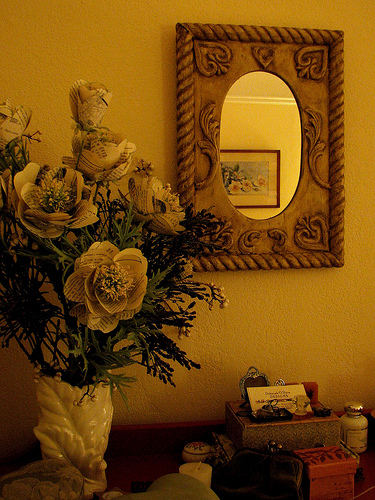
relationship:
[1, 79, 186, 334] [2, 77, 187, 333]
roses made from newspaper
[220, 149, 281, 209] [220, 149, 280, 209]
reflection of art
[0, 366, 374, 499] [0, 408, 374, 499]
knick knacks on table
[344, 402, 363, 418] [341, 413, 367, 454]
cap on jar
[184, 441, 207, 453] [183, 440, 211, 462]
flowers on porcelain box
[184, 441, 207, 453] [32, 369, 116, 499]
flowers in vase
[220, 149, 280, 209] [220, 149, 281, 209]
art in reflection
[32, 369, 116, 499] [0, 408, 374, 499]
vase on table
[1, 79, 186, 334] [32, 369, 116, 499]
roses in vase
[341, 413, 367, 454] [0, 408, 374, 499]
jar on table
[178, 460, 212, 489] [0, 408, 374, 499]
candle on table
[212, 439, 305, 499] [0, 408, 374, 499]
coin purse on table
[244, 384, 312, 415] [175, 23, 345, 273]
business card under mirror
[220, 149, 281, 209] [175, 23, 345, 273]
reflection in mirror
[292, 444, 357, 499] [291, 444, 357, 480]
box has a lid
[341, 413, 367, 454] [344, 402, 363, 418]
jar has a cap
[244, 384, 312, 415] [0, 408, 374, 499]
business card on table